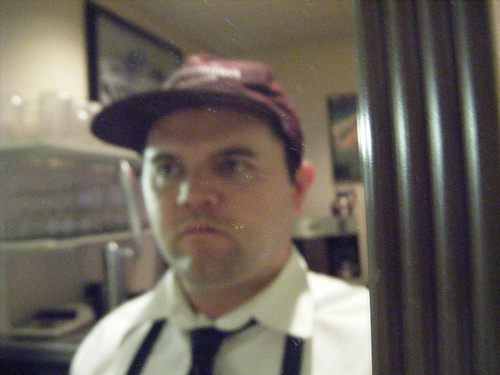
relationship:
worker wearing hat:
[66, 49, 372, 374] [78, 50, 304, 156]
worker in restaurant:
[66, 49, 372, 374] [2, 2, 497, 371]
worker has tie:
[66, 49, 372, 374] [181, 325, 227, 370]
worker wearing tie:
[66, 49, 372, 374] [181, 325, 227, 370]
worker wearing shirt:
[66, 49, 372, 374] [50, 245, 373, 370]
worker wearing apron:
[66, 49, 372, 374] [126, 319, 309, 371]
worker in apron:
[66, 49, 372, 374] [126, 319, 309, 371]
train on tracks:
[329, 113, 359, 151] [338, 146, 359, 162]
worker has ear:
[66, 49, 372, 374] [292, 160, 316, 210]